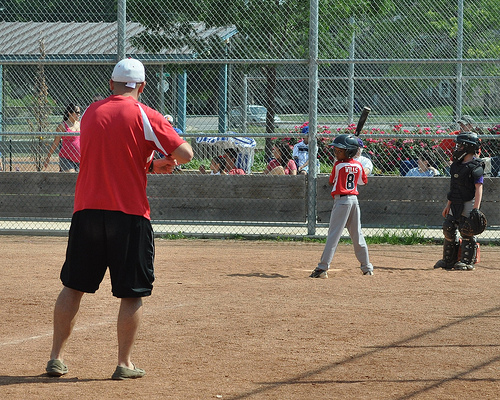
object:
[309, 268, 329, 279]
shoes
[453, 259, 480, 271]
shoes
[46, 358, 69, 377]
shoes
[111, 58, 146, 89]
hat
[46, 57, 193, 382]
coach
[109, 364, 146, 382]
loafers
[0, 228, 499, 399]
ground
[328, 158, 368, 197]
shirt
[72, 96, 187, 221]
shirt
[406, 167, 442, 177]
shirt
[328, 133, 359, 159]
helmet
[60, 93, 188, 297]
baseball uniform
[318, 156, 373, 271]
baseball uniform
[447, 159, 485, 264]
baseball uniform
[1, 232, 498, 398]
field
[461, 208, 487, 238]
mitt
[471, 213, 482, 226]
hand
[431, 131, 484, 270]
boy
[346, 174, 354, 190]
number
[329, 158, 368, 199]
jersey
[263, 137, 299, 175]
woman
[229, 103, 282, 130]
car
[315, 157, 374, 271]
uniform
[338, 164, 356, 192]
back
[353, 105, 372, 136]
baseball bat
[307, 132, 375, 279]
child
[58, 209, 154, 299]
shorts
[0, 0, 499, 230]
fence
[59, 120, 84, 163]
shirt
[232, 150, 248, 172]
lot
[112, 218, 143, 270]
black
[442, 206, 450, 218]
hand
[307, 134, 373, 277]
batter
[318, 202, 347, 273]
leg